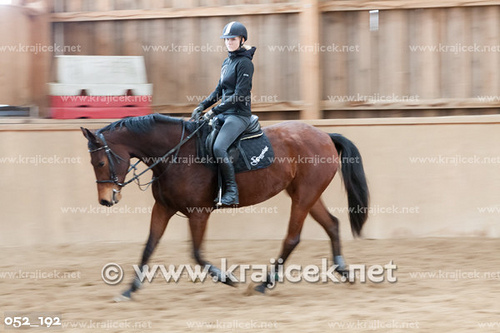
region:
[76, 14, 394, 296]
Girl riding a horse.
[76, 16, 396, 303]
Girl is sitting upright.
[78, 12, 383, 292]
Girl is wearing a helmet.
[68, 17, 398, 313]
The helmet has a stripe.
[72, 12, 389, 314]
The helmet is black.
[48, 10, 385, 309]
The stripe is black.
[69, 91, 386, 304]
Horse has black tail.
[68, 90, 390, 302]
Horse has black mane.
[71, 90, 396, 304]
Horse is brown and black.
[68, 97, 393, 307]
Horse has his head down.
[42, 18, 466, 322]
woman rides a horse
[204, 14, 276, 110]
she wears a helmet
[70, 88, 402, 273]
the horse is brown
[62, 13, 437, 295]
they are in motion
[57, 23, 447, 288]
she is riding indoors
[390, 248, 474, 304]
the floor is sandy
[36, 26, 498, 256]
she has a black jacket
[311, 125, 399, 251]
the tail is black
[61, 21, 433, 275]
the sport is equestrian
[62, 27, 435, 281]
horseback riding in a pen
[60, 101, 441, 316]
A horse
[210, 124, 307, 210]
A horse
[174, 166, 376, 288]
A horse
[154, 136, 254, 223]
A horse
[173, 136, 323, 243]
A horse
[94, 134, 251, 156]
A horse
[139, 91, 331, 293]
A horse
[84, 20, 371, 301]
a woman riding a brown horse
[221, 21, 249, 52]
head of a woman wearing a helmet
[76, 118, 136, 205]
the head of a horse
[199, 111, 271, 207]
left leg of a woman wearing leather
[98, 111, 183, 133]
a horse's mane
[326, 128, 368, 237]
the tail of a horse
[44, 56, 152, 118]
a red and white cooler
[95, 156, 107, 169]
the eye of a horse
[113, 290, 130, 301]
the hoof of a horse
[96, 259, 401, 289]
copyright watermark for krajicek.net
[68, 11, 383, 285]
a woman riding a horse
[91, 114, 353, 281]
a brown horse in motion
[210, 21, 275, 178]
a woman wearing black riding a horse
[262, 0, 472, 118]
wooden fence surrounding the pen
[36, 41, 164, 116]
a red and white supply box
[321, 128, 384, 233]
black tail of the horse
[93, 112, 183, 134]
black mane of the horse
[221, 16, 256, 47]
the woman's black helmet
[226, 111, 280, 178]
a black saddle on the horse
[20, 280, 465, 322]
brown dirt of the pen